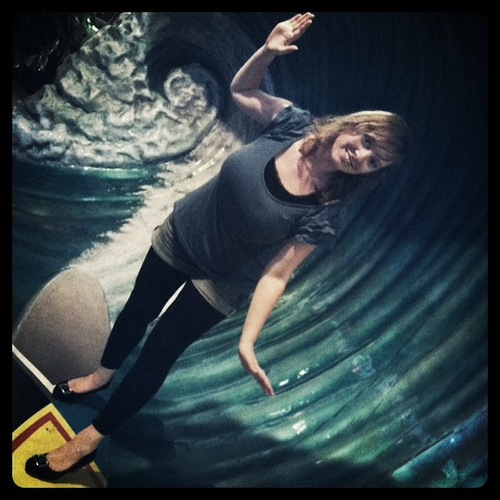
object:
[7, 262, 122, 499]
surfboard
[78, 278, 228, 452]
leg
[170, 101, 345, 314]
shirt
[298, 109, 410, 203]
blonde hair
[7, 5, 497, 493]
photo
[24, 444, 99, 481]
heels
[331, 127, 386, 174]
face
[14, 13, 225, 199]
water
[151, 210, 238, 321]
grey shorts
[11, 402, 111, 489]
mat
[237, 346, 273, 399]
hand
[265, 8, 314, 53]
hand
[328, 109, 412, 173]
head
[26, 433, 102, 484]
feet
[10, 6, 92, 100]
rocks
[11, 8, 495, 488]
floor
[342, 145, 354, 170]
smile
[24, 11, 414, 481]
female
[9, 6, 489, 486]
tube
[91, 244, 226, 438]
pants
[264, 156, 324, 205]
undershirt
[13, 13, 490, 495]
illusion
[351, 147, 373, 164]
nose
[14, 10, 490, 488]
tunnel